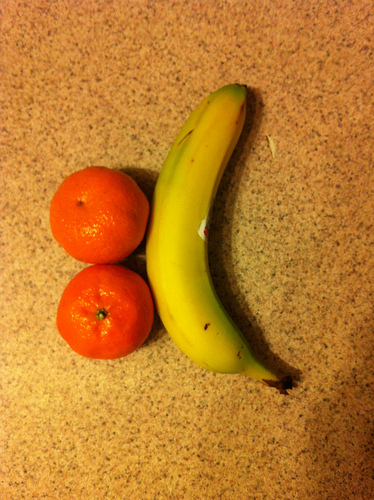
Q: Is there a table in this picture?
A: Yes, there is a table.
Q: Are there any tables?
A: Yes, there is a table.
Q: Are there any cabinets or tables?
A: Yes, there is a table.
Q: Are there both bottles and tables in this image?
A: No, there is a table but no bottles.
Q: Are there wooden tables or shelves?
A: Yes, there is a wood table.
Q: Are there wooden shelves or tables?
A: Yes, there is a wood table.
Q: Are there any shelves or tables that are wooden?
A: Yes, the table is wooden.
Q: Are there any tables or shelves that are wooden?
A: Yes, the table is wooden.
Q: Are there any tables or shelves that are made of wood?
A: Yes, the table is made of wood.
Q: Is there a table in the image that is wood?
A: Yes, there is a wood table.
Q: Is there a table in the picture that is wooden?
A: Yes, there is a table that is wooden.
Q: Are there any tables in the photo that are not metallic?
A: Yes, there is a wooden table.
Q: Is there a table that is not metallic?
A: Yes, there is a wooden table.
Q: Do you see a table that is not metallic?
A: Yes, there is a wooden table.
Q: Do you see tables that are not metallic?
A: Yes, there is a wooden table.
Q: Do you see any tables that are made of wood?
A: Yes, there is a table that is made of wood.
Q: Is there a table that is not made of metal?
A: Yes, there is a table that is made of wood.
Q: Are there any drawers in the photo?
A: No, there are no drawers.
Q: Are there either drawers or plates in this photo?
A: No, there are no drawers or plates.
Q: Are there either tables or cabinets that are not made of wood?
A: No, there is a table but it is made of wood.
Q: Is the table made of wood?
A: Yes, the table is made of wood.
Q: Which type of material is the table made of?
A: The table is made of wood.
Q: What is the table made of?
A: The table is made of wood.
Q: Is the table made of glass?
A: No, the table is made of wood.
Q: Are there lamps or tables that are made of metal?
A: No, there is a table but it is made of wood.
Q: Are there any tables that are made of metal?
A: No, there is a table but it is made of wood.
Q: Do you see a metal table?
A: No, there is a table but it is made of wood.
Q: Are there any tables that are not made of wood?
A: No, there is a table but it is made of wood.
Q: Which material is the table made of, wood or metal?
A: The table is made of wood.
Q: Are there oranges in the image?
A: Yes, there are oranges.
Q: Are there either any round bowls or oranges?
A: Yes, there are round oranges.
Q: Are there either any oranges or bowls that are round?
A: Yes, the oranges are round.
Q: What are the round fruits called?
A: The fruits are oranges.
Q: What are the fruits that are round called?
A: The fruits are oranges.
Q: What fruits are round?
A: The fruits are oranges.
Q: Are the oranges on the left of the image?
A: Yes, the oranges are on the left of the image.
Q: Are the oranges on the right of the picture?
A: No, the oranges are on the left of the image.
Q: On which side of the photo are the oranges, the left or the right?
A: The oranges are on the left of the image.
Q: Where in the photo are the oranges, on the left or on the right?
A: The oranges are on the left of the image.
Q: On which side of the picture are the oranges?
A: The oranges are on the left of the image.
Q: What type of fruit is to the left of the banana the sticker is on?
A: The fruits are oranges.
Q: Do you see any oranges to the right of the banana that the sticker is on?
A: No, the oranges are to the left of the banana.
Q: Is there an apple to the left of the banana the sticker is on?
A: No, there are oranges to the left of the banana.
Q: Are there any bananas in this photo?
A: Yes, there is a banana.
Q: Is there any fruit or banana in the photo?
A: Yes, there is a banana.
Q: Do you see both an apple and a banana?
A: No, there is a banana but no apples.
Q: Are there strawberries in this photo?
A: No, there are no strawberries.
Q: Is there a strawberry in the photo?
A: No, there are no strawberries.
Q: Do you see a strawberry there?
A: No, there are no strawberries.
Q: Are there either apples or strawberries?
A: No, there are no strawberries or apples.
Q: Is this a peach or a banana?
A: This is a banana.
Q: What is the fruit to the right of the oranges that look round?
A: The fruit is a banana.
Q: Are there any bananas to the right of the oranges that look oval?
A: Yes, there is a banana to the right of the oranges.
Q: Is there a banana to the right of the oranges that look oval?
A: Yes, there is a banana to the right of the oranges.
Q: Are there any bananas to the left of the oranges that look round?
A: No, the banana is to the right of the oranges.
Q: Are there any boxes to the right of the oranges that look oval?
A: No, there is a banana to the right of the oranges.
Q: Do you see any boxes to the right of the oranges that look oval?
A: No, there is a banana to the right of the oranges.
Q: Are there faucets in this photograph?
A: No, there are no faucets.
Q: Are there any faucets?
A: No, there are no faucets.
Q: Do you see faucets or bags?
A: No, there are no faucets or bags.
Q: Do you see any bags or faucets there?
A: No, there are no faucets or bags.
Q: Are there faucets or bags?
A: No, there are no faucets or bags.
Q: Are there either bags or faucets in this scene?
A: No, there are no faucets or bags.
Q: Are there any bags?
A: No, there are no bags.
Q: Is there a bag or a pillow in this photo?
A: No, there are no bags or pillows.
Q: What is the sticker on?
A: The sticker is on the banana.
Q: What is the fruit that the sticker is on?
A: The fruit is a banana.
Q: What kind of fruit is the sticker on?
A: The sticker is on the banana.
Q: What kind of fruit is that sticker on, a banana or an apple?
A: The sticker is on a banana.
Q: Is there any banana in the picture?
A: Yes, there is a banana.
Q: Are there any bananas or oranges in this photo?
A: Yes, there is a banana.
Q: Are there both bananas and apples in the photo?
A: No, there is a banana but no apples.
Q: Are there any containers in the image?
A: No, there are no containers.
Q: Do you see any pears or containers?
A: No, there are no containers or pears.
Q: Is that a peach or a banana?
A: That is a banana.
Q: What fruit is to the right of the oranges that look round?
A: The fruit is a banana.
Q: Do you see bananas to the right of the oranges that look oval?
A: Yes, there is a banana to the right of the oranges.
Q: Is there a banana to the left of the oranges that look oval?
A: No, the banana is to the right of the oranges.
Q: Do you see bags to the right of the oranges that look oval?
A: No, there is a banana to the right of the oranges.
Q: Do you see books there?
A: No, there are no books.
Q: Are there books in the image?
A: No, there are no books.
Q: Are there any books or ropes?
A: No, there are no books or ropes.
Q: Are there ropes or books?
A: No, there are no books or ropes.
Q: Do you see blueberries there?
A: No, there are no blueberries.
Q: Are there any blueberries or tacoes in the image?
A: No, there are no blueberries or tacoes.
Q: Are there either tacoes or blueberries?
A: No, there are no blueberries or tacoes.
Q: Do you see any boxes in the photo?
A: No, there are no boxes.